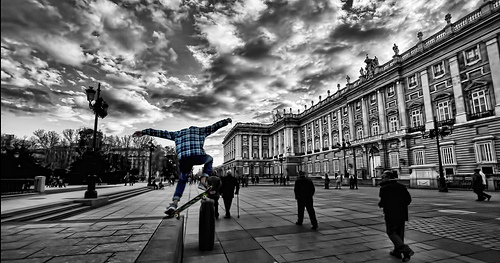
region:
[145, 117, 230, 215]
this is a boy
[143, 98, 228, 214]
the boy is skating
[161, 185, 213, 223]
he is using a skate board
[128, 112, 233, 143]
the boys hands are part on air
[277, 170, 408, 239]
the people are walking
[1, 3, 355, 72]
the clouds are grey in color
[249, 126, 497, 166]
the building is beside the people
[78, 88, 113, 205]
this is a street light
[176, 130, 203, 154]
the boy has blue stripped shirt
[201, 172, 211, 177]
the boys trousers is folded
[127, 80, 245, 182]
boys blue plaid jacket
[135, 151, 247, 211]
turned up pant legs on blue jeans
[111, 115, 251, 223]
a young person skate boarding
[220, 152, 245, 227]
a man walking with a cane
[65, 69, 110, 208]
a black street light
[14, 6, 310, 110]
a very cloudy sky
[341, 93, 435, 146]
Upper level pillars on building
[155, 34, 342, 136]
sun tries to show from behind clouds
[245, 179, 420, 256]
Wide paved walking area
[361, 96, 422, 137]
arches placed above second floor windows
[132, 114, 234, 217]
Bright blue and black shirt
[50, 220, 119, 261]
stone walkway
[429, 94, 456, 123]
Large windows on building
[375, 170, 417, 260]
balding man walking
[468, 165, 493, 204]
two people walking near building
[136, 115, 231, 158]
long sleeve blue and black checkered shirt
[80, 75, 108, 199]
pole with lights on top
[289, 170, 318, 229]
man walking on road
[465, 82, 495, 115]
second story windows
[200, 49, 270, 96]
clouds in the sky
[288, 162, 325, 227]
a person in the street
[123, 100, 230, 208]
a person in the street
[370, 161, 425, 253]
a person in the street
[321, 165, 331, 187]
a person in the street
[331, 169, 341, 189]
a person in the street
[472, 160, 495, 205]
a person in the street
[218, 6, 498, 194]
a large building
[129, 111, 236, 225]
a person skating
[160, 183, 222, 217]
a skate board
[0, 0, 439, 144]
the clouds in the sky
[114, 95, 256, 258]
A person skate boarding in road.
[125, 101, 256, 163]
Blue and black jacket.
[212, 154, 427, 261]
PEOPLE WALKING IN THE STREET.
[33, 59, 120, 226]
Tall black double lamp post.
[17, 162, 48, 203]
White trash can on sidewalk.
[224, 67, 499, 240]
Black and white photo.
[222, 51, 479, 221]
Tall building near street.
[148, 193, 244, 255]
Skateboard balancing on another skateboard.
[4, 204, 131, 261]
Brick pattern o a street.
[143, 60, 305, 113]
Gray and white sky.